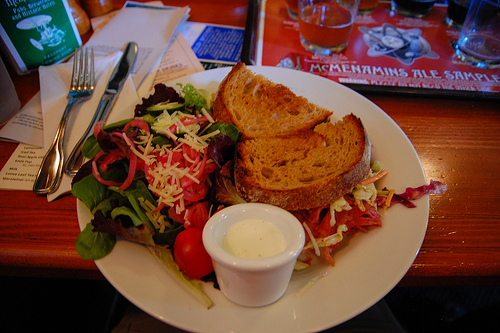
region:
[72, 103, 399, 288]
the plate is white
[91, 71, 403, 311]
white plate full of food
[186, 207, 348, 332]
white sauce in dish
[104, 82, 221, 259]
salad on white plate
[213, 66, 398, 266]
cut sandwich on plate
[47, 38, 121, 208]
fork and knife on napkin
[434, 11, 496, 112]
glass sitting on tray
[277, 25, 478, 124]
red and white tray on table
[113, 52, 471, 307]
white plate on table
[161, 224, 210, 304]
cherry tomato on plate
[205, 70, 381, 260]
toasted bread on sandwich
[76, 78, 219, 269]
A salad.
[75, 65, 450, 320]
A plate of food.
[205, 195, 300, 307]
A small container with salad dressing.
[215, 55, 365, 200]
Two pieces of toasted bread.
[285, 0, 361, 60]
A glass with a drink in it.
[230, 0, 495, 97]
A menu.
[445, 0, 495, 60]
An empty glass.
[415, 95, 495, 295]
A wooden table.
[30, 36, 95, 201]
A stainless steel fork.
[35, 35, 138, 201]
The silverware is on top of a napkin.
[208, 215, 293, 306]
side of salad dressing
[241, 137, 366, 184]
slice of toast on plate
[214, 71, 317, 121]
slice of toast on plate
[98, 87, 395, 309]
salad on white plate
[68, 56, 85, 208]
silver fork on napkin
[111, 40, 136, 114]
silver knife on napkin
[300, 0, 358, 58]
beer on sample menu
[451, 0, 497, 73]
beer on sample menu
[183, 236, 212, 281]
red tomato in salad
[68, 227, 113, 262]
piece of green lettuce in salad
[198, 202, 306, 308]
a cup of ranch dressing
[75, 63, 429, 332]
a plate full of food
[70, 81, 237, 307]
a green salad with vegetables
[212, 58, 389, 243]
a grilled meat and cheese sandwhich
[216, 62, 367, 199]
two pieces of toasted bread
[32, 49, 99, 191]
a metal four tined fork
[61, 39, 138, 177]
a metal table knife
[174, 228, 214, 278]
a small red tomato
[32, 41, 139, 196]
a knife and fork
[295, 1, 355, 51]
bottom of a glass